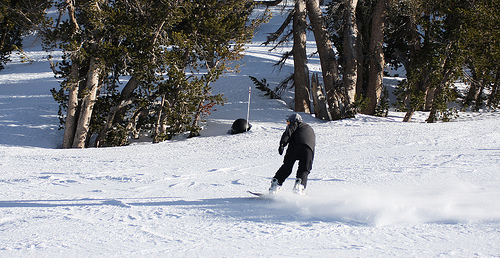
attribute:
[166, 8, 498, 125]
trees — tall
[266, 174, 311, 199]
boots — white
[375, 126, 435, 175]
snow — white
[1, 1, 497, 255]
snow — white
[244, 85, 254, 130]
metal pole — white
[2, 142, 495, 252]
snow — white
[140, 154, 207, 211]
snow — white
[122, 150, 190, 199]
snow — white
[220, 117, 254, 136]
object — black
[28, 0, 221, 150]
woods — shaded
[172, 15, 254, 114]
trees — evergreen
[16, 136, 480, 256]
snow — white